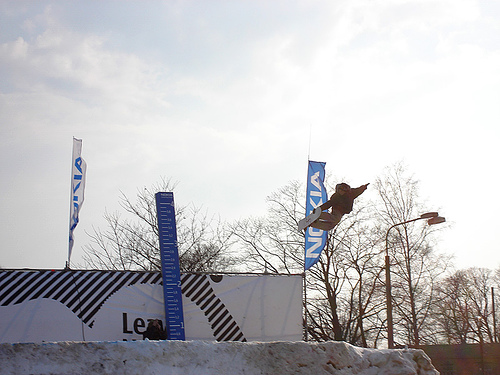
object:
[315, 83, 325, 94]
clouds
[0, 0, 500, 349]
sky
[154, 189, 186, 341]
board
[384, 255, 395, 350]
pole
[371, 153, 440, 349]
tree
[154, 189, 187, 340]
ruler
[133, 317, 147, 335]
letter e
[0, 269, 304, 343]
banner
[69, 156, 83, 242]
nokia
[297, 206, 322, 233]
board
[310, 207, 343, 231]
pants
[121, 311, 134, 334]
letter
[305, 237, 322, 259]
white n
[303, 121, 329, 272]
blue fabric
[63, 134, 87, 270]
banner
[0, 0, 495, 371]
wind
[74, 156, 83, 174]
letters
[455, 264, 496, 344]
trees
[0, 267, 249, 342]
pattern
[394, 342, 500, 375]
wall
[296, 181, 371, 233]
trick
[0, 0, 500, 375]
air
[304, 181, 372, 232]
man